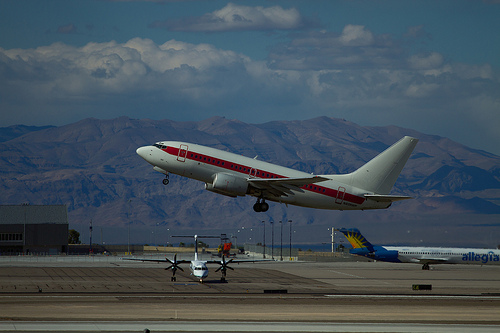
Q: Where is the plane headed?
A: Up in the air.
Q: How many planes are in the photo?
A: 3.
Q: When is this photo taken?
A: In the daytime.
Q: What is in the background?
A: Mountain.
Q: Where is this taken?
A: On a runway.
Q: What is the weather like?
A: It is slightly cloudy.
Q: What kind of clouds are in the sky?
A: Clear fluffy clouds.